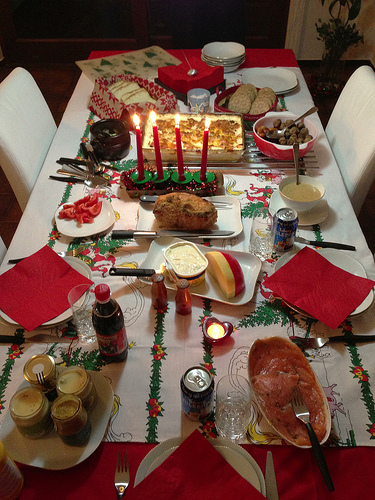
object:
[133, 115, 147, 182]
candle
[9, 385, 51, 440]
jar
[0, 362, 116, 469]
plate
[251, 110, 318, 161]
bowl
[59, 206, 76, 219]
tomatoes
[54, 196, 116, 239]
plate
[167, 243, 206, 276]
butter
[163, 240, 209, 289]
tub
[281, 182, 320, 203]
soup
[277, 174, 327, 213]
bowl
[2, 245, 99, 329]
napkin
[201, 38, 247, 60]
bowls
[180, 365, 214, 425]
can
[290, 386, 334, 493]
fork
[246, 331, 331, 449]
bowl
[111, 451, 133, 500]
fork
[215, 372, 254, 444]
glass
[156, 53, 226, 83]
napkins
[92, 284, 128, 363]
bottle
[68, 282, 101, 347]
glass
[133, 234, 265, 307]
plate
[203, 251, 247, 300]
cheese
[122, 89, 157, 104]
bread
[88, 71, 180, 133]
containter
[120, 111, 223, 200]
center piece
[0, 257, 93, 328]
plate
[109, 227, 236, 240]
knife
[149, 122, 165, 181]
candles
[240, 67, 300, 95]
plates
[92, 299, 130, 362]
soda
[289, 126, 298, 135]
meatballs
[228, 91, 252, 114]
cookies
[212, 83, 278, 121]
plate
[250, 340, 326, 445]
potatoes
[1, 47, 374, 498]
table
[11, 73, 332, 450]
meal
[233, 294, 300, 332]
tree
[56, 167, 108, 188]
utensils